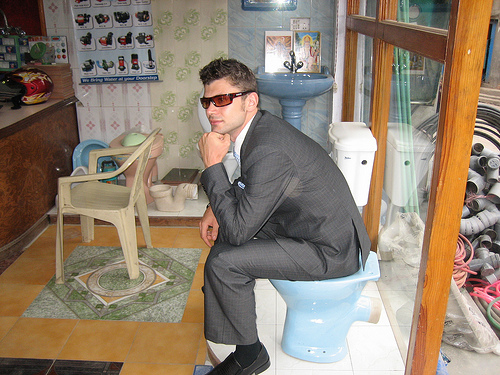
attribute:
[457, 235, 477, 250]
cords — orange, extension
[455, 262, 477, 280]
cords — orange, extension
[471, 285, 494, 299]
cords — orange, extension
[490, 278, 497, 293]
cords — orange, extension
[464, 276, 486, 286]
cords — orange, extension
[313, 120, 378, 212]
back — white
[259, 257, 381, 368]
toilet — light, blue, bottom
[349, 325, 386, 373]
tile — top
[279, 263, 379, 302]
toilet seat — blue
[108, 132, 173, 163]
toilet seat — blue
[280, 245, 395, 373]
seat — blue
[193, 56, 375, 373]
man — sitting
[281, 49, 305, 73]
faucet — silver, bathroom, water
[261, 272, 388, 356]
toilet seat — blue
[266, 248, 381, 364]
toilet seat — blue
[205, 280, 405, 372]
tile — top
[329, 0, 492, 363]
window — large, partition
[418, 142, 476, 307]
trim — wooden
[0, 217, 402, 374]
tile — top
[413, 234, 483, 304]
ball — orange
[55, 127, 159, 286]
chair — tan, plastic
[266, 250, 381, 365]
toliet — blue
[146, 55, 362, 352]
man — sitting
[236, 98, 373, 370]
toilet — blue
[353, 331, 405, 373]
tile — top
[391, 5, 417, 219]
curtain — green, shower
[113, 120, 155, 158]
ball — orange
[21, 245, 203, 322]
design — green, tiled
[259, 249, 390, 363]
toilet seat — blue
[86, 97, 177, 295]
chair — beige, plastic, lawn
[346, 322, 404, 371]
tile — top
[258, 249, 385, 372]
seat — toilet, blue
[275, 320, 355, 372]
tile — top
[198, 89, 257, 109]
glasses — dark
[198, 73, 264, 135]
face — mans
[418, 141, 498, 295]
amount — large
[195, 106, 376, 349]
suit — gray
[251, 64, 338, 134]
sink — light blue, blue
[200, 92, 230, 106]
eyes — mans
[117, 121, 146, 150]
ball — orange